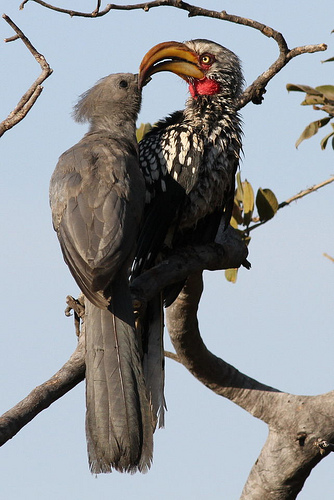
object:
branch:
[156, 265, 334, 498]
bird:
[137, 40, 241, 308]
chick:
[49, 71, 164, 479]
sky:
[49, 23, 118, 68]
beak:
[135, 41, 203, 87]